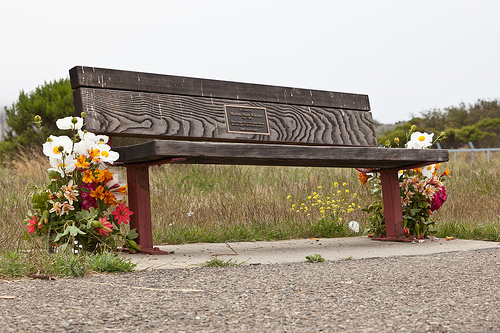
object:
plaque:
[224, 104, 269, 134]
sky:
[0, 0, 499, 125]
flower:
[24, 113, 132, 244]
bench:
[70, 66, 449, 256]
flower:
[288, 181, 362, 218]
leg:
[371, 170, 410, 241]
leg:
[124, 162, 168, 256]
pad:
[116, 233, 494, 268]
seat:
[112, 139, 449, 166]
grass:
[0, 150, 499, 279]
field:
[2, 149, 499, 284]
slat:
[71, 65, 446, 162]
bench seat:
[109, 137, 450, 165]